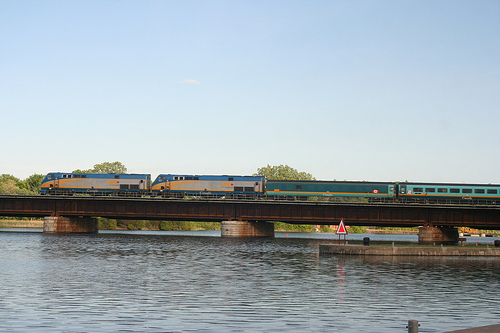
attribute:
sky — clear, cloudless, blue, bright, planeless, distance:
[46, 27, 452, 144]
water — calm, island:
[49, 252, 441, 328]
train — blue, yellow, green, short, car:
[37, 173, 496, 205]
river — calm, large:
[19, 239, 491, 328]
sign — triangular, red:
[330, 218, 353, 232]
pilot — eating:
[44, 176, 52, 184]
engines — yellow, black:
[41, 165, 265, 199]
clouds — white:
[90, 68, 332, 124]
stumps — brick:
[209, 216, 295, 245]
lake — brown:
[59, 231, 280, 321]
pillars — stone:
[33, 212, 113, 241]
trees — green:
[19, 158, 172, 232]